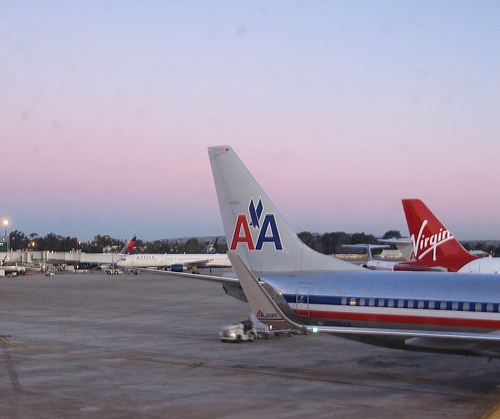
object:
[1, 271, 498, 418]
ground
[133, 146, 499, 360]
plane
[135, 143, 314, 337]
tail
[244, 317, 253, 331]
man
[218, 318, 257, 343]
tram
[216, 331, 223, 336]
headlights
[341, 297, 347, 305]
window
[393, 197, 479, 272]
tail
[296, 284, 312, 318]
door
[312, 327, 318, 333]
light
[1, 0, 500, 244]
sky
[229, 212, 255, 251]
letter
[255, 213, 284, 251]
letter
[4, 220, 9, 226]
light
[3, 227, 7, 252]
pole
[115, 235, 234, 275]
plane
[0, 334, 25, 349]
line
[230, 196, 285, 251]
logo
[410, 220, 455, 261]
word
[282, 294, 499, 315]
stripe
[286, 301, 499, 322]
line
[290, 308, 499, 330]
line